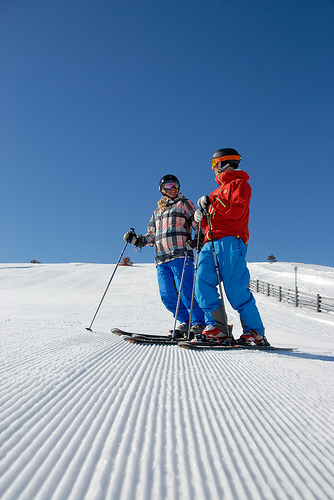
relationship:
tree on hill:
[263, 254, 277, 266] [246, 262, 321, 304]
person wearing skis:
[191, 145, 267, 348] [177, 336, 298, 353]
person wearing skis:
[123, 175, 202, 339] [110, 327, 192, 348]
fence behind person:
[247, 274, 333, 317] [191, 145, 267, 348]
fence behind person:
[247, 274, 333, 317] [123, 175, 202, 339]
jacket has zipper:
[199, 169, 254, 245] [206, 175, 224, 241]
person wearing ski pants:
[191, 145, 267, 348] [193, 236, 266, 339]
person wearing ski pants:
[123, 175, 202, 339] [154, 253, 201, 328]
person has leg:
[191, 145, 267, 348] [193, 241, 227, 332]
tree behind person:
[263, 254, 277, 266] [191, 145, 267, 348]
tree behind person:
[263, 254, 277, 266] [123, 175, 202, 339]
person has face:
[123, 175, 202, 339] [163, 182, 181, 200]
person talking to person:
[191, 145, 267, 348] [123, 175, 202, 339]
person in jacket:
[191, 145, 267, 348] [199, 169, 254, 245]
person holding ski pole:
[191, 145, 267, 348] [202, 207, 234, 348]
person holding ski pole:
[191, 145, 267, 348] [186, 216, 201, 343]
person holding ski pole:
[123, 175, 202, 339] [171, 239, 191, 342]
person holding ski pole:
[123, 175, 202, 339] [87, 227, 134, 332]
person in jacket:
[123, 175, 202, 339] [131, 193, 199, 266]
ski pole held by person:
[87, 227, 134, 332] [123, 175, 202, 339]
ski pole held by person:
[171, 239, 191, 342] [123, 175, 202, 339]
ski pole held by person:
[186, 216, 201, 343] [191, 145, 267, 348]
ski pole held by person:
[202, 207, 234, 348] [191, 145, 267, 348]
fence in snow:
[247, 274, 333, 317] [0, 258, 332, 498]